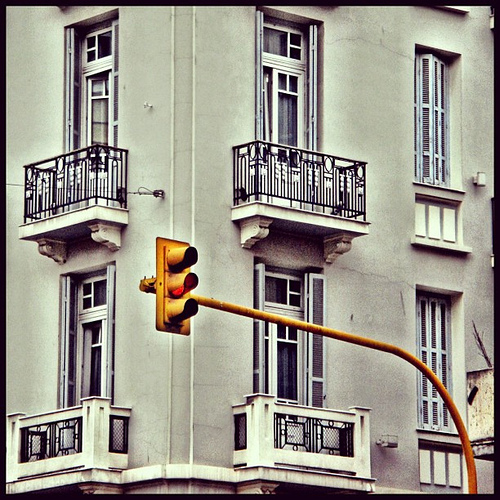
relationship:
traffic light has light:
[142, 232, 486, 495] [167, 272, 190, 298]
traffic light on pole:
[142, 232, 486, 495] [148, 279, 489, 500]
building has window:
[6, 7, 491, 494] [411, 44, 458, 187]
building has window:
[6, 7, 491, 494] [414, 288, 463, 437]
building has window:
[6, 7, 491, 494] [77, 273, 116, 306]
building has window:
[6, 7, 491, 494] [75, 19, 115, 63]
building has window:
[6, 7, 491, 494] [261, 17, 314, 65]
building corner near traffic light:
[156, 6, 211, 500] [142, 232, 486, 495]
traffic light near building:
[142, 232, 486, 495] [6, 7, 491, 494]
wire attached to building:
[6, 178, 169, 206] [6, 7, 491, 494]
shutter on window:
[413, 48, 436, 185] [411, 44, 458, 187]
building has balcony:
[6, 7, 491, 494] [18, 142, 127, 234]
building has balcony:
[6, 7, 491, 494] [235, 392, 371, 481]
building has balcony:
[6, 7, 491, 494] [8, 395, 132, 484]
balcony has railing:
[230, 140, 369, 220] [232, 140, 369, 215]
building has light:
[6, 7, 491, 494] [464, 164, 498, 197]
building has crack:
[6, 7, 491, 494] [327, 259, 416, 294]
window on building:
[261, 17, 314, 65] [6, 7, 491, 494]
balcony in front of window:
[230, 140, 369, 220] [261, 17, 314, 65]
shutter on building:
[413, 48, 435, 183] [6, 7, 491, 494]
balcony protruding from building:
[18, 142, 127, 234] [6, 7, 491, 494]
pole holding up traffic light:
[148, 279, 489, 500] [142, 232, 486, 495]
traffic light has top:
[142, 232, 486, 495] [153, 237, 194, 270]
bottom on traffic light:
[153, 291, 197, 330] [142, 232, 486, 495]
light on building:
[167, 272, 190, 298] [6, 7, 491, 494]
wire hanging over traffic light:
[6, 178, 169, 206] [142, 232, 486, 495]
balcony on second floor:
[18, 142, 127, 234] [4, 5, 485, 268]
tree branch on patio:
[466, 318, 493, 369] [464, 367, 494, 456]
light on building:
[464, 164, 498, 197] [6, 7, 491, 494]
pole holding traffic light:
[148, 279, 489, 500] [142, 232, 486, 495]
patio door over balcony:
[77, 63, 115, 160] [18, 142, 127, 234]